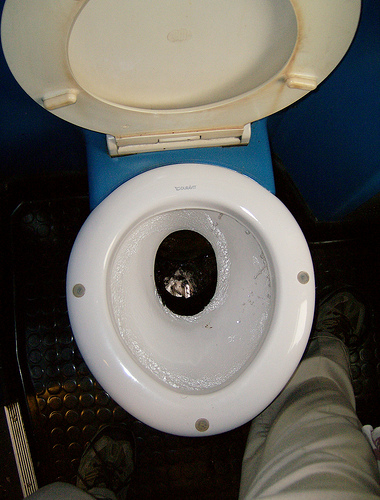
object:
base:
[147, 229, 226, 321]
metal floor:
[34, 365, 82, 415]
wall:
[9, 63, 371, 235]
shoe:
[69, 419, 141, 498]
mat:
[14, 298, 159, 498]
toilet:
[77, 159, 280, 422]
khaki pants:
[277, 406, 353, 498]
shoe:
[312, 287, 368, 347]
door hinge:
[4, 401, 37, 498]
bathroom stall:
[5, 2, 375, 497]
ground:
[283, 148, 309, 176]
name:
[171, 182, 200, 194]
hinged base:
[107, 124, 252, 158]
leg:
[257, 293, 369, 498]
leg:
[29, 416, 145, 497]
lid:
[0, 0, 360, 157]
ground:
[267, 114, 296, 137]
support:
[86, 131, 277, 188]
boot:
[318, 266, 376, 356]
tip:
[105, 424, 136, 443]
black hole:
[153, 225, 219, 317]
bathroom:
[3, 1, 362, 497]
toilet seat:
[1, 2, 368, 164]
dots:
[293, 270, 310, 287]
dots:
[193, 416, 209, 435]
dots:
[71, 283, 84, 299]